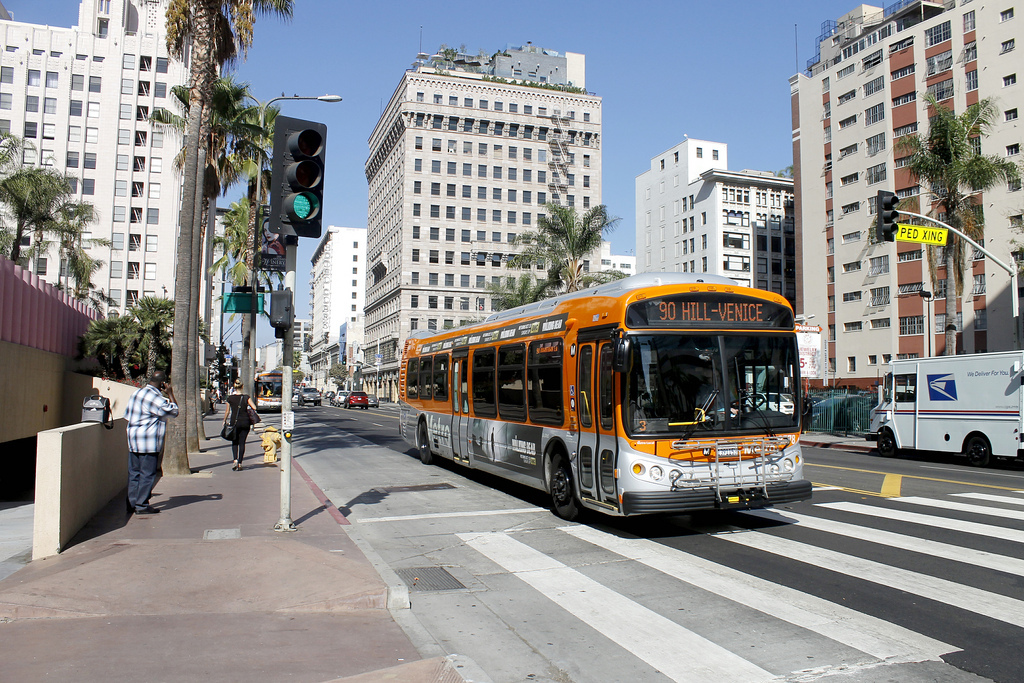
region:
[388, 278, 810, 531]
The orange bus.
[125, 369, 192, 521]
MAN TALKING ON THE PHONE.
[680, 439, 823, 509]
The bike rack on the bus.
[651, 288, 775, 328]
Sign on the bus.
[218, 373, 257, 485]
The woman wearing all black.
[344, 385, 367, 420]
The red car driving.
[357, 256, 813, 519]
a bus on a street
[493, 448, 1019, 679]
white lines onthe road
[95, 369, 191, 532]
the man is wearing a plaid shirt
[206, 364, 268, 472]
back of a lady walking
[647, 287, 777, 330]
words on a board on bus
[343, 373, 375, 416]
the back of red car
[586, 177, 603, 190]
window on the building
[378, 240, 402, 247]
window on the building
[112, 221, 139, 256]
window on the building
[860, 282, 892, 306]
window on the building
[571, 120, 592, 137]
window on the building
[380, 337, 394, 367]
window on the building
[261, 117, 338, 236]
it is a traffic light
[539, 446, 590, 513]
the front tire of the bus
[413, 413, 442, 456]
the back tire of the bus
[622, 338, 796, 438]
it is the wind shield of the bus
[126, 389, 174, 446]
a blue and white shirt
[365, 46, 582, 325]
a large white builidng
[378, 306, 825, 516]
A white and orange bus on the road.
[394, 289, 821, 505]
orange and gray bus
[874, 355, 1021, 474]
white USPS truck parked on the road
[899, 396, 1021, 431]
blue and red stripes on USPS truck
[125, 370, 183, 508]
man in blue plaid shirt talking on phone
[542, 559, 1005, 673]
white lines painted on road for pedestrians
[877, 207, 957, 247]
yellow sign that reads "Ped Xing"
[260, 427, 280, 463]
yellow fire hydrant on the road side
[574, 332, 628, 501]
orange and gray bus door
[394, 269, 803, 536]
the bus is on the road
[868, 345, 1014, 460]
the truck is white in color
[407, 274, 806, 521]
the bus is grey and orange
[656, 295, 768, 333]
the route sign is on top of the bus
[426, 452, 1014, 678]
stripes are painted on the crossing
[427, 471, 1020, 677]
the stripes are white in color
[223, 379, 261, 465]
a woman is walking on the sidewalk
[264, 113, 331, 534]
the traffic is on a pole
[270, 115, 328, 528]
stoplight on sidewalk is green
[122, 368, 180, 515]
man in checked shirt and blue pants on sidwalk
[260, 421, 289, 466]
yellow fire hydrant on sidewalk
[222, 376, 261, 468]
woman wearing black walking on sidewalk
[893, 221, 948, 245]
Yellow Ped Xing Sign above street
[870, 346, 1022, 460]
white postal truck parked on street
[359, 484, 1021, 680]
white crosswalk stripes on street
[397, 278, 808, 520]
white and orange bus driving on street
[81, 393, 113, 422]
black messenger bag on wall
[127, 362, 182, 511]
man is on the cellphone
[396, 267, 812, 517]
bus is stopped before cross walk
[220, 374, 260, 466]
lady is walking down the side walk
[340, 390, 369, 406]
car is driving down the street